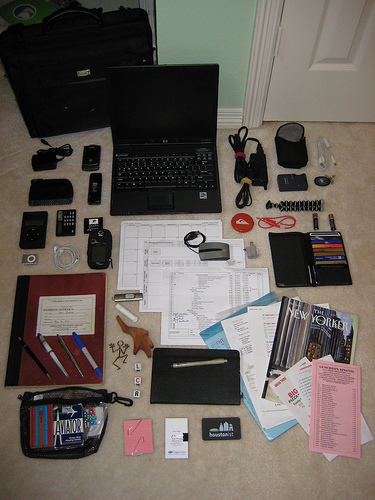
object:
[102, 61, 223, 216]
laptop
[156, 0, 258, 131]
wall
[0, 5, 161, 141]
bag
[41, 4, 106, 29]
handle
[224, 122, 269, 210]
cord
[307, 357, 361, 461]
page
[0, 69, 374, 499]
floor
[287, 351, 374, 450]
page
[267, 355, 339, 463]
page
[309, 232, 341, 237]
credit cards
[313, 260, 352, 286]
slots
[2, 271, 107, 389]
notebook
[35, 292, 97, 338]
label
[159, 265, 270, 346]
block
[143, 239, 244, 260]
block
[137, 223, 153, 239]
block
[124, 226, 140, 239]
blocks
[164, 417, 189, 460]
card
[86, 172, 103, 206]
battery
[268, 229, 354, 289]
wallet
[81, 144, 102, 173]
battery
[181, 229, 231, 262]
mouse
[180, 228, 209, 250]
cord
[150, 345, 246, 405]
case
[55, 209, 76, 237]
calculator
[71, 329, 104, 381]
pen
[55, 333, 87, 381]
pen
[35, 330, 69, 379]
pen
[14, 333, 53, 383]
pen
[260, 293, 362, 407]
pamphlet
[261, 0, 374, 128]
door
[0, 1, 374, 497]
room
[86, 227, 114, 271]
ipod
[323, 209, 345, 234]
usb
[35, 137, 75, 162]
cable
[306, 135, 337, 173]
earphones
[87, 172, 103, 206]
remote control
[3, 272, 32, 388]
black binder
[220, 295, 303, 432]
pamplets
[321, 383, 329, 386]
black words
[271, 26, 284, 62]
hinge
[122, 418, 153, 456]
card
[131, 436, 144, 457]
clips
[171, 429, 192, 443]
clip